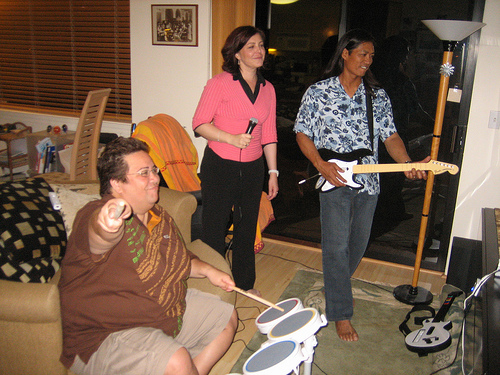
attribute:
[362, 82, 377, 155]
strap — long, black, guitar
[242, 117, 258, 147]
microphone — black and silver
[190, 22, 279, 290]
woman — smiling, young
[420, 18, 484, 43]
shade — white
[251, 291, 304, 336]
drum — grey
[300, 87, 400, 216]
shirt — blue and white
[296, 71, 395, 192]
shirt — blue, pattern, dark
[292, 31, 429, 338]
man — young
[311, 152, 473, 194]
guitar — white, black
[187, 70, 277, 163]
sweater — pink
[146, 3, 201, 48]
picture — framed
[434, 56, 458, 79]
bow — silver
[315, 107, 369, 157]
pattern — blue